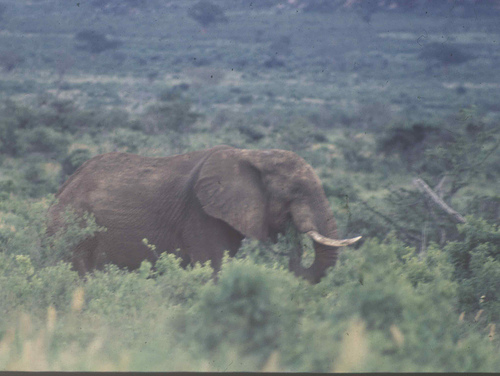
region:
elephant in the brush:
[26, 118, 381, 332]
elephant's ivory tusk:
[293, 219, 369, 267]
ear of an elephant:
[183, 129, 278, 250]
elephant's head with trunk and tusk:
[276, 145, 363, 287]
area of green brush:
[40, 274, 353, 362]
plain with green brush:
[15, 15, 405, 136]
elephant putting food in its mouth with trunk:
[43, 156, 385, 313]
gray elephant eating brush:
[23, 132, 375, 308]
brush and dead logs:
[373, 147, 483, 288]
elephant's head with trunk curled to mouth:
[200, 130, 386, 315]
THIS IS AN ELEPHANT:
[40, 141, 374, 292]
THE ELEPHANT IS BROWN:
[34, 140, 363, 290]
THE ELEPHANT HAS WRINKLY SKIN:
[37, 137, 362, 304]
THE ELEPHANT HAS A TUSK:
[306, 227, 370, 261]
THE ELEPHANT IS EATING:
[271, 204, 331, 289]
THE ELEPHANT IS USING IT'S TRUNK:
[279, 215, 344, 290]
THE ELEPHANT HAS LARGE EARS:
[186, 143, 271, 258]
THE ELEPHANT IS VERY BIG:
[38, 128, 365, 301]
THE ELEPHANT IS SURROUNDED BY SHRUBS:
[39, 140, 364, 301]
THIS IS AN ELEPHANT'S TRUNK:
[277, 203, 358, 284]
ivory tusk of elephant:
[310, 231, 366, 249]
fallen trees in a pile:
[366, 116, 492, 266]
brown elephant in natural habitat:
[43, 143, 343, 290]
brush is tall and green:
[3, 275, 496, 369]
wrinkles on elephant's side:
[101, 184, 189, 251]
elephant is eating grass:
[284, 225, 349, 296]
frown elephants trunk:
[283, 231, 348, 287]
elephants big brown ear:
[193, 144, 268, 244]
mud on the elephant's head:
[218, 148, 323, 180]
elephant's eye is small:
[286, 183, 303, 202]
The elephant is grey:
[55, 136, 350, 276]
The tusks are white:
[292, 223, 377, 257]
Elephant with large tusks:
[50, 111, 377, 311]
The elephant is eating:
[11, 112, 401, 327]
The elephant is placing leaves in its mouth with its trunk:
[58, 155, 381, 286]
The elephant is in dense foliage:
[50, 137, 368, 302]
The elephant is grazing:
[41, 128, 366, 298]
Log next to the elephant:
[379, 156, 491, 261]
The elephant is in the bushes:
[15, 139, 400, 342]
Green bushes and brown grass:
[20, 26, 460, 373]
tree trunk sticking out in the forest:
[411, 178, 440, 201]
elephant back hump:
[87, 153, 132, 171]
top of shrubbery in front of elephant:
[221, 260, 274, 282]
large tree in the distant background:
[191, 4, 217, 25]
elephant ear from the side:
[198, 162, 270, 239]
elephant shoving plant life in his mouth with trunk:
[278, 211, 300, 241]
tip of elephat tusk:
[355, 236, 362, 241]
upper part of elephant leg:
[179, 221, 226, 261]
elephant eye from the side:
[287, 186, 302, 195]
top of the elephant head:
[252, 151, 303, 184]